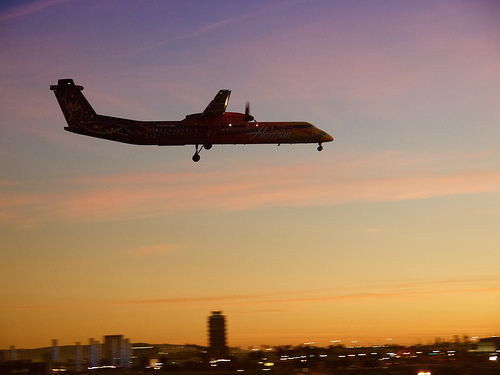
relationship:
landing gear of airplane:
[191, 142, 214, 164] [46, 76, 335, 163]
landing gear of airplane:
[316, 142, 326, 152] [46, 76, 335, 163]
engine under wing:
[177, 112, 256, 129] [196, 87, 235, 130]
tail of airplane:
[49, 78, 101, 136] [46, 76, 335, 163]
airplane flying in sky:
[46, 76, 335, 163] [0, 0, 499, 349]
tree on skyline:
[433, 334, 443, 346] [0, 309, 499, 374]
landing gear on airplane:
[191, 142, 214, 164] [46, 76, 335, 163]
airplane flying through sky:
[46, 76, 335, 163] [0, 0, 499, 349]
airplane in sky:
[46, 76, 335, 163] [0, 0, 499, 349]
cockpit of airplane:
[285, 119, 315, 136] [46, 76, 335, 163]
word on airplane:
[245, 125, 294, 142] [46, 76, 335, 163]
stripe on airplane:
[315, 129, 328, 142] [46, 76, 335, 163]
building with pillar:
[204, 307, 231, 363] [207, 306, 217, 324]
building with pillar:
[204, 307, 231, 363] [214, 309, 227, 324]